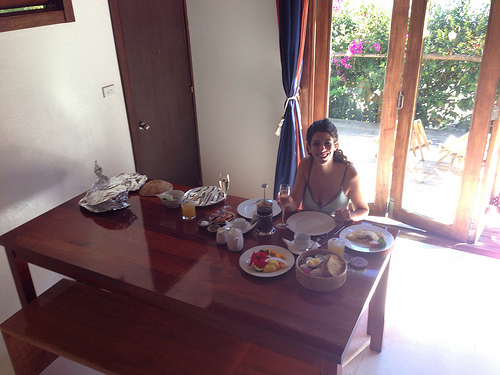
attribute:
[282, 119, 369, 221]
woman — eating, sitting, drinking, smiling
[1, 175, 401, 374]
table — covered, wooden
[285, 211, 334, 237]
plate — empty, white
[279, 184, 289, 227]
glass — white, pink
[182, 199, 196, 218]
orange juice — glass, small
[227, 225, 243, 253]
tea pot — white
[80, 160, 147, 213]
foil — aluminum, tin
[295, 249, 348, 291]
basket — tan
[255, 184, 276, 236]
coffee press — french, small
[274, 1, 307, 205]
curtain — hanging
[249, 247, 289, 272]
food — colorful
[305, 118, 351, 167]
hair — black, dark, long, brown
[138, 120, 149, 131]
handle — silver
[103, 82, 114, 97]
switch — electrical, white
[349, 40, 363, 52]
flower — purple, pin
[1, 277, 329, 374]
bench — brown